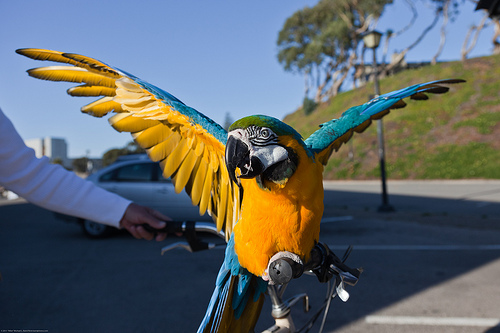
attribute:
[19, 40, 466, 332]
parrot — blue, gold, yellow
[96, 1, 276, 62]
sky — blue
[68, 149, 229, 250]
vehicle — silver, parked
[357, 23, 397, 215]
lamp — black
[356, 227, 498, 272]
stripe — white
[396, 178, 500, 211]
sidewalk — paved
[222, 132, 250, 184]
beak — black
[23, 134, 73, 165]
building — white